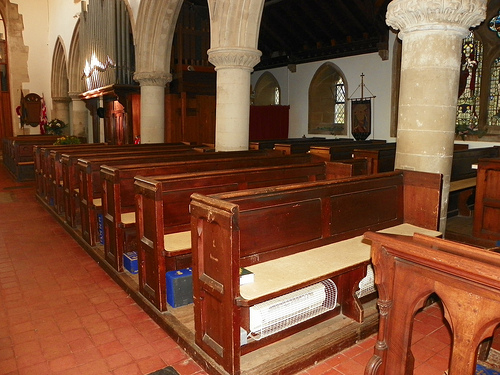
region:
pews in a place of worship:
[28, 143, 367, 326]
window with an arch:
[300, 62, 350, 137]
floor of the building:
[21, 210, 162, 355]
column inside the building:
[360, 8, 477, 251]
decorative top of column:
[381, 3, 491, 46]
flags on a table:
[12, 83, 49, 130]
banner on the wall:
[346, 68, 373, 148]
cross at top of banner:
[355, 70, 369, 85]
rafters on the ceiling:
[264, 9, 370, 51]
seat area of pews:
[247, 225, 419, 245]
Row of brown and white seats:
[28, 118, 473, 374]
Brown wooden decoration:
[361, 213, 499, 371]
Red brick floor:
[4, 172, 479, 374]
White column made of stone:
[364, 1, 478, 325]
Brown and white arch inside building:
[118, 3, 293, 169]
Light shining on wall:
[49, 33, 129, 135]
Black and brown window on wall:
[296, 46, 372, 144]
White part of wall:
[235, 36, 426, 166]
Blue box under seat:
[148, 256, 215, 332]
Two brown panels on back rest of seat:
[222, 186, 423, 265]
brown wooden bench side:
[187, 194, 238, 370]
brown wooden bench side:
[132, 173, 166, 307]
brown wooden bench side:
[99, 165, 124, 273]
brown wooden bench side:
[74, 159, 98, 246]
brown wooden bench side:
[61, 156, 74, 226]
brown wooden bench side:
[37, 149, 52, 204]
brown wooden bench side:
[392, 172, 437, 229]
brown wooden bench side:
[320, 160, 350, 180]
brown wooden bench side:
[350, 149, 378, 171]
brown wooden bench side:
[309, 144, 330, 158]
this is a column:
[120, 66, 371, 164]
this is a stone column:
[362, 141, 437, 150]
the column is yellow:
[354, 93, 471, 150]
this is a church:
[48, 164, 213, 346]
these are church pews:
[225, 231, 406, 326]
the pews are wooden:
[220, 166, 272, 225]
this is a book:
[236, 254, 276, 308]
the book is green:
[242, 279, 252, 286]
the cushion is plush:
[295, 251, 305, 280]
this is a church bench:
[356, 219, 496, 374]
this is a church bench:
[191, 172, 458, 324]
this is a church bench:
[132, 163, 371, 270]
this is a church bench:
[90, 152, 297, 259]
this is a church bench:
[34, 133, 219, 252]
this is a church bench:
[29, 135, 142, 229]